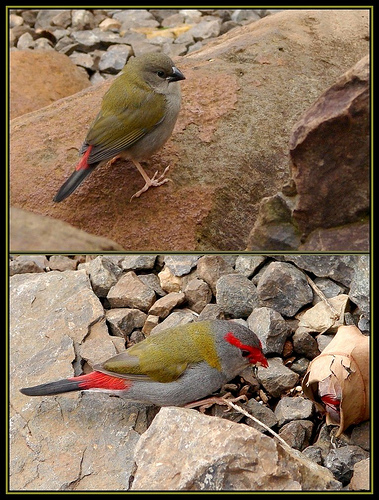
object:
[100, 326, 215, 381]
feathers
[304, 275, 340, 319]
twig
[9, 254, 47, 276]
rocks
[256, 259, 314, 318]
rocks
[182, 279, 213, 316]
rocks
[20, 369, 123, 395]
feathers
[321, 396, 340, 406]
item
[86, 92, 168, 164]
wing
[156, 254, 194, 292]
rock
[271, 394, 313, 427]
rock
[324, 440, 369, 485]
rock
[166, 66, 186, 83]
beak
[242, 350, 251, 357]
eye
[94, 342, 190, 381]
wing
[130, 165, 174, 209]
brown foot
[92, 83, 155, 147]
leafy green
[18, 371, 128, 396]
tail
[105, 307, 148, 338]
rock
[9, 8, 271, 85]
ground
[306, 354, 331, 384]
leaf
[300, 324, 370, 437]
trash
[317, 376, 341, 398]
leaf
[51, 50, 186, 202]
bird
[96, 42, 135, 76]
rock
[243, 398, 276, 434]
small rocks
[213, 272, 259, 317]
brown grey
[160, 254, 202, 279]
brown grey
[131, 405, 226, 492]
brown grey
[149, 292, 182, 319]
brown grey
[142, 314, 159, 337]
rocks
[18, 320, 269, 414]
bird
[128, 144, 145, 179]
leg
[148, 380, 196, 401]
belly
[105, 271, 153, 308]
pebble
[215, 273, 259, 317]
pebble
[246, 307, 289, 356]
pebble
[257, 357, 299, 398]
pebble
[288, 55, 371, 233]
rock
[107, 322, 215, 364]
back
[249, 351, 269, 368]
beak